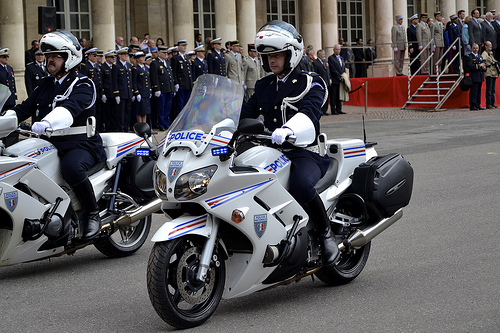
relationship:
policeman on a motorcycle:
[239, 20, 338, 267] [147, 72, 415, 327]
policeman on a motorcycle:
[13, 31, 105, 241] [0, 82, 162, 268]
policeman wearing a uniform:
[13, 31, 105, 241] [3, 68, 107, 185]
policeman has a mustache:
[13, 31, 105, 241] [48, 61, 55, 66]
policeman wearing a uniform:
[239, 20, 338, 267] [231, 69, 329, 203]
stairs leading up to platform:
[399, 39, 464, 110] [328, 75, 499, 108]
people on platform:
[339, 6, 499, 77] [328, 75, 499, 108]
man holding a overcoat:
[328, 43, 352, 116] [339, 67, 350, 102]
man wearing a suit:
[328, 43, 352, 116] [328, 54, 344, 112]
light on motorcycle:
[212, 145, 229, 156] [147, 72, 415, 327]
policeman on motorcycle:
[239, 20, 338, 267] [147, 72, 415, 327]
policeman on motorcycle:
[13, 31, 105, 241] [0, 82, 162, 268]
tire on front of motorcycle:
[145, 235, 225, 328] [147, 72, 415, 327]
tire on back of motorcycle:
[312, 197, 372, 284] [147, 72, 415, 327]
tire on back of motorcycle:
[94, 186, 152, 257] [0, 82, 162, 268]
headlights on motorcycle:
[153, 162, 218, 201] [147, 72, 415, 327]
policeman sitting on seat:
[239, 20, 338, 267] [313, 157, 338, 194]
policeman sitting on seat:
[13, 31, 105, 241] [85, 150, 107, 174]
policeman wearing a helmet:
[239, 20, 338, 267] [253, 20, 304, 72]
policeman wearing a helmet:
[13, 31, 105, 241] [38, 28, 84, 73]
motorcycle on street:
[147, 72, 415, 327] [0, 116, 498, 331]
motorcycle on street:
[0, 82, 162, 268] [0, 116, 498, 331]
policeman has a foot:
[239, 20, 338, 267] [323, 231, 341, 265]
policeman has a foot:
[13, 31, 105, 241] [81, 214, 104, 240]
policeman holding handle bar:
[239, 20, 338, 267] [232, 131, 297, 146]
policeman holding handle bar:
[13, 31, 105, 241] [16, 121, 54, 139]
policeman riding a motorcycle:
[13, 31, 105, 241] [0, 82, 162, 268]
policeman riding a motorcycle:
[239, 20, 338, 267] [147, 72, 415, 327]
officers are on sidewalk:
[0, 34, 352, 133] [119, 101, 499, 133]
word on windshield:
[167, 132, 204, 142] [167, 72, 245, 139]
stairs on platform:
[399, 39, 464, 110] [328, 75, 499, 108]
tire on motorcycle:
[145, 235, 225, 328] [147, 72, 415, 327]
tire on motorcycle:
[312, 197, 372, 284] [147, 72, 415, 327]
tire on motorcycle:
[94, 186, 152, 257] [0, 82, 162, 268]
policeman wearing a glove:
[13, 31, 105, 241] [29, 120, 47, 134]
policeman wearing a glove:
[239, 20, 338, 267] [271, 127, 292, 143]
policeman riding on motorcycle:
[239, 20, 338, 267] [147, 72, 415, 327]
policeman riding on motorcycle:
[13, 31, 105, 241] [0, 82, 162, 268]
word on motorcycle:
[167, 132, 204, 142] [147, 72, 415, 327]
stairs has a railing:
[399, 39, 464, 110] [406, 35, 463, 103]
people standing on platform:
[339, 6, 499, 77] [328, 75, 499, 108]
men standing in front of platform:
[462, 40, 499, 110] [328, 75, 499, 108]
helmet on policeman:
[253, 20, 304, 72] [239, 20, 338, 267]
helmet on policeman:
[38, 28, 84, 73] [13, 31, 105, 241]